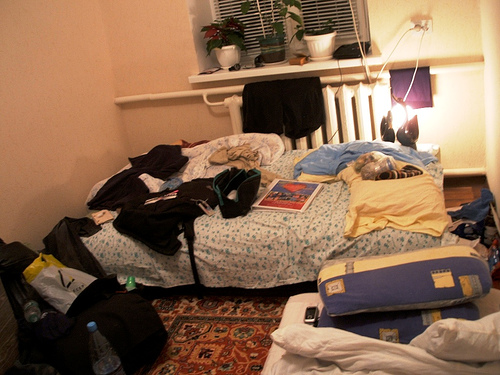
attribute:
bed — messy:
[68, 139, 448, 300]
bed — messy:
[138, 149, 383, 229]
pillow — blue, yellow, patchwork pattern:
[314, 236, 499, 320]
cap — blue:
[81, 310, 108, 332]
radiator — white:
[221, 75, 390, 152]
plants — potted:
[196, 1, 343, 68]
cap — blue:
[83, 316, 93, 331]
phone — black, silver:
[304, 304, 319, 325]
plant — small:
[203, 13, 243, 45]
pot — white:
[217, 44, 245, 74]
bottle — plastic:
[85, 317, 127, 372]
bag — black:
[215, 162, 262, 214]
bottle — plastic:
[123, 275, 135, 292]